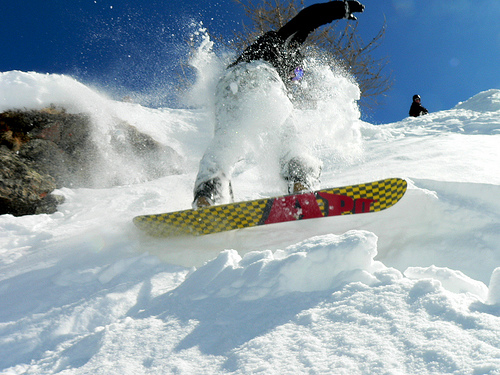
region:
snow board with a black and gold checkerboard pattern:
[127, 175, 409, 237]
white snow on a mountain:
[1, 248, 483, 365]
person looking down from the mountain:
[408, 92, 428, 117]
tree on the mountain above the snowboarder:
[338, 24, 386, 96]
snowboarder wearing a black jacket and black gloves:
[141, 2, 407, 243]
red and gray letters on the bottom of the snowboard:
[256, 191, 376, 216]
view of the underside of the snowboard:
[128, 177, 405, 243]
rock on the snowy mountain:
[1, 109, 134, 214]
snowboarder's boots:
[191, 163, 321, 210]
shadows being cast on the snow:
[40, 253, 286, 328]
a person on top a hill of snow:
[404, 87, 431, 121]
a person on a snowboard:
[128, 2, 411, 252]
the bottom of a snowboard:
[127, 173, 407, 244]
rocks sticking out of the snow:
[2, 111, 77, 216]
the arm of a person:
[274, 1, 366, 38]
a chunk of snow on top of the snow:
[177, 227, 384, 316]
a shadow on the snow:
[152, 288, 332, 357]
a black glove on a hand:
[340, 1, 367, 25]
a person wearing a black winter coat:
[225, 0, 344, 75]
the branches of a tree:
[250, 0, 285, 30]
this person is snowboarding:
[123, 1, 432, 246]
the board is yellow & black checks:
[136, 178, 423, 249]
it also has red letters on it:
[263, 183, 380, 223]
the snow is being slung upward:
[163, 34, 398, 263]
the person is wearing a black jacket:
[228, 0, 364, 76]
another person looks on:
[406, 83, 434, 127]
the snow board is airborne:
[113, 175, 425, 259]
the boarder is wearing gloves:
[330, 3, 366, 30]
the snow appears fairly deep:
[127, 231, 451, 368]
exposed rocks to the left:
[4, 115, 146, 235]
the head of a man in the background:
[411, 93, 423, 103]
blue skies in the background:
[18, 14, 78, 56]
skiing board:
[137, 211, 249, 228]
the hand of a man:
[336, 0, 366, 21]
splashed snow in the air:
[302, 71, 359, 146]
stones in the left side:
[5, 150, 45, 197]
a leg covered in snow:
[200, 157, 222, 199]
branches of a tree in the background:
[344, 33, 371, 68]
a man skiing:
[233, 25, 306, 181]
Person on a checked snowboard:
[124, 185, 409, 228]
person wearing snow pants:
[198, 75, 304, 182]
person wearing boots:
[178, 162, 325, 198]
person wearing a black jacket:
[243, 0, 361, 65]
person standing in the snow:
[393, 85, 427, 129]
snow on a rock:
[10, 63, 92, 98]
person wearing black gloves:
[334, 3, 364, 16]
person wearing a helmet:
[411, 93, 421, 103]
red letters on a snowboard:
[257, 187, 377, 224]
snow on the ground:
[181, 232, 411, 344]